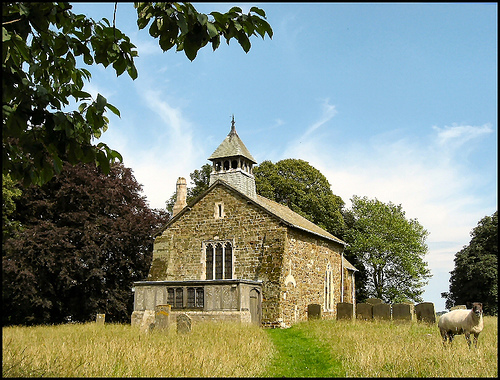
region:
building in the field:
[114, 120, 355, 373]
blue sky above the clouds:
[364, 63, 440, 137]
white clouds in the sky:
[412, 123, 464, 185]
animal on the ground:
[421, 283, 493, 372]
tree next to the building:
[36, 200, 128, 299]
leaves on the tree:
[39, 98, 104, 161]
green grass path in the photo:
[270, 325, 321, 368]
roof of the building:
[265, 171, 320, 226]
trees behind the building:
[295, 120, 435, 240]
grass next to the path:
[61, 341, 101, 371]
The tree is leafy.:
[7, 12, 125, 112]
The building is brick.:
[152, 184, 368, 348]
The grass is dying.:
[307, 329, 410, 379]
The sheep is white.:
[435, 294, 492, 351]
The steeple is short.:
[188, 102, 275, 198]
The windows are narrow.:
[193, 229, 253, 282]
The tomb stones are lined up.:
[293, 292, 450, 341]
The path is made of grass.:
[246, 309, 343, 376]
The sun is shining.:
[27, 0, 489, 367]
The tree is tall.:
[343, 191, 446, 316]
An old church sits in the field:
[125, 150, 400, 340]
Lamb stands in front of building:
[424, 295, 491, 342]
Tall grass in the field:
[45, 332, 125, 374]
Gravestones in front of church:
[94, 292, 206, 328]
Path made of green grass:
[260, 330, 312, 376]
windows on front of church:
[200, 215, 255, 275]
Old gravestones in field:
[320, 295, 450, 320]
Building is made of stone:
[243, 210, 313, 287]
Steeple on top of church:
[210, 116, 282, 196]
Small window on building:
[213, 200, 230, 220]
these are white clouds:
[130, 84, 498, 283]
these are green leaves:
[13, 118, 115, 279]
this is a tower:
[201, 121, 269, 213]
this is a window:
[201, 236, 232, 283]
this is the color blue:
[376, 85, 395, 105]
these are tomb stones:
[301, 290, 447, 335]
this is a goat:
[426, 290, 486, 353]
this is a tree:
[322, 182, 444, 329]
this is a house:
[121, 122, 377, 349]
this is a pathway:
[231, 308, 344, 377]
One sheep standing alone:
[407, 286, 492, 361]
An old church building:
[116, 116, 382, 346]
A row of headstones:
[300, 298, 450, 346]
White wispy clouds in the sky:
[106, 86, 478, 269]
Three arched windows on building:
[193, 228, 251, 295]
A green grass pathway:
[263, 316, 331, 379]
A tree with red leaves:
[4, 153, 160, 322]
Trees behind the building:
[161, 131, 426, 318]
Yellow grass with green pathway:
[13, 313, 490, 378]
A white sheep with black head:
[417, 293, 487, 360]